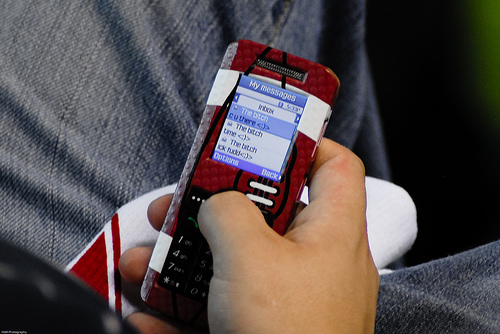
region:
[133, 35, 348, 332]
this is a mobile phone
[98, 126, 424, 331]
this is a hand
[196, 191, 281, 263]
this is a thumb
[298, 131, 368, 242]
this is a finger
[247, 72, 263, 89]
this is a word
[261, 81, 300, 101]
this is a tall tree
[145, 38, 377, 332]
cell phone in hand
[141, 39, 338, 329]
cell phone in football case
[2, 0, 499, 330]
blue jeans on two legs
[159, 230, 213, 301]
white numbers on black buttons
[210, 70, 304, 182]
words on glowing screen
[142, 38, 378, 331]
thumb on keypad of phone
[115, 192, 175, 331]
tips of three fingers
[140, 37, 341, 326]
two white lines on phone cover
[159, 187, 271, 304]
keypad on surface of phone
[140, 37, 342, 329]
audio speaker on top of phone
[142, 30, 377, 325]
hand holding device with messages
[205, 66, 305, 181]
blue and white screen listing messages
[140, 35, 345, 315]
divice cover resembling football texture and laces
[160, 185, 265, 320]
thumb over black panel on device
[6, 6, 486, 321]
user wearing denim jeans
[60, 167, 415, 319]
white and red object under device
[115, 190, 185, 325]
fingertips under device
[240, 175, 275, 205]
two white stripes in black border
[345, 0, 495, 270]
dark space between pair of jeans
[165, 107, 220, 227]
bumpy dots on side of device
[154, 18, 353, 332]
a cell phone bar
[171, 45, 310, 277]
an old cell phone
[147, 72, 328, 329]
an old cell phone with case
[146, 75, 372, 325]
a hand holding a cell phone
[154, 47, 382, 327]
a hand holding phone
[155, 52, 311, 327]
a phone turned on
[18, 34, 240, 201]
a person wearing jeans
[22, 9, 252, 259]
a person wearing blue jeans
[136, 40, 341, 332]
red cell phone in a person's hand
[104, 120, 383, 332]
hand holding a cell phone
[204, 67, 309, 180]
screen on a cell phone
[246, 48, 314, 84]
speaker on a cell phone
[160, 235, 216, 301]
number pad on the phone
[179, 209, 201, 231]
green button on the phone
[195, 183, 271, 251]
person's right thumb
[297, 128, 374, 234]
person's right index finger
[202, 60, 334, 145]
white stripe on a phone case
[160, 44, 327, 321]
A mobile phone in the hands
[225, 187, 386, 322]
A person holding a phone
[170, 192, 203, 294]
Keypad on the phone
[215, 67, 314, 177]
Screen on the cellphone